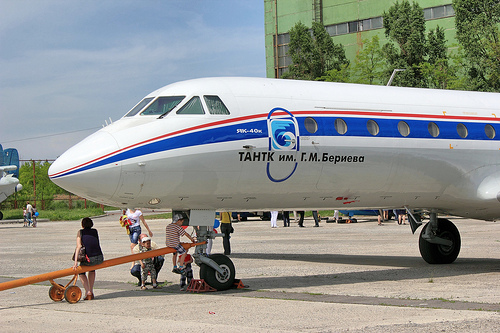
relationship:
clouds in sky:
[0, 0, 266, 170] [0, 0, 267, 167]